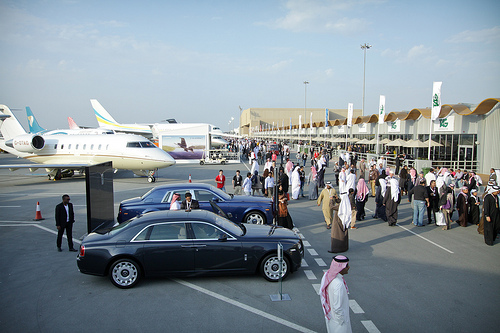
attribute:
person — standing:
[56, 194, 78, 251]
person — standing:
[318, 255, 350, 333]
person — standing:
[215, 169, 227, 190]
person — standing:
[409, 177, 432, 227]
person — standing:
[232, 170, 244, 196]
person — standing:
[426, 180, 439, 224]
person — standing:
[327, 188, 354, 253]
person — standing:
[480, 184, 500, 246]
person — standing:
[182, 192, 199, 209]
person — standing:
[168, 191, 184, 210]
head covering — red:
[320, 253, 346, 314]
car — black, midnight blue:
[78, 200, 306, 288]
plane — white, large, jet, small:
[0, 105, 177, 183]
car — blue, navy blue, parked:
[117, 183, 275, 227]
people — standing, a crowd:
[217, 135, 499, 250]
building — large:
[226, 99, 499, 207]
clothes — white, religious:
[319, 270, 352, 332]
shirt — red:
[216, 174, 226, 187]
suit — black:
[55, 202, 75, 248]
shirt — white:
[63, 204, 71, 221]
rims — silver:
[266, 258, 286, 278]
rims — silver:
[113, 262, 136, 286]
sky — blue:
[0, 2, 499, 134]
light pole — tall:
[357, 42, 372, 114]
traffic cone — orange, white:
[35, 201, 46, 223]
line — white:
[176, 278, 317, 332]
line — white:
[35, 225, 83, 244]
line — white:
[0, 204, 22, 210]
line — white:
[395, 222, 455, 254]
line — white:
[364, 207, 375, 215]